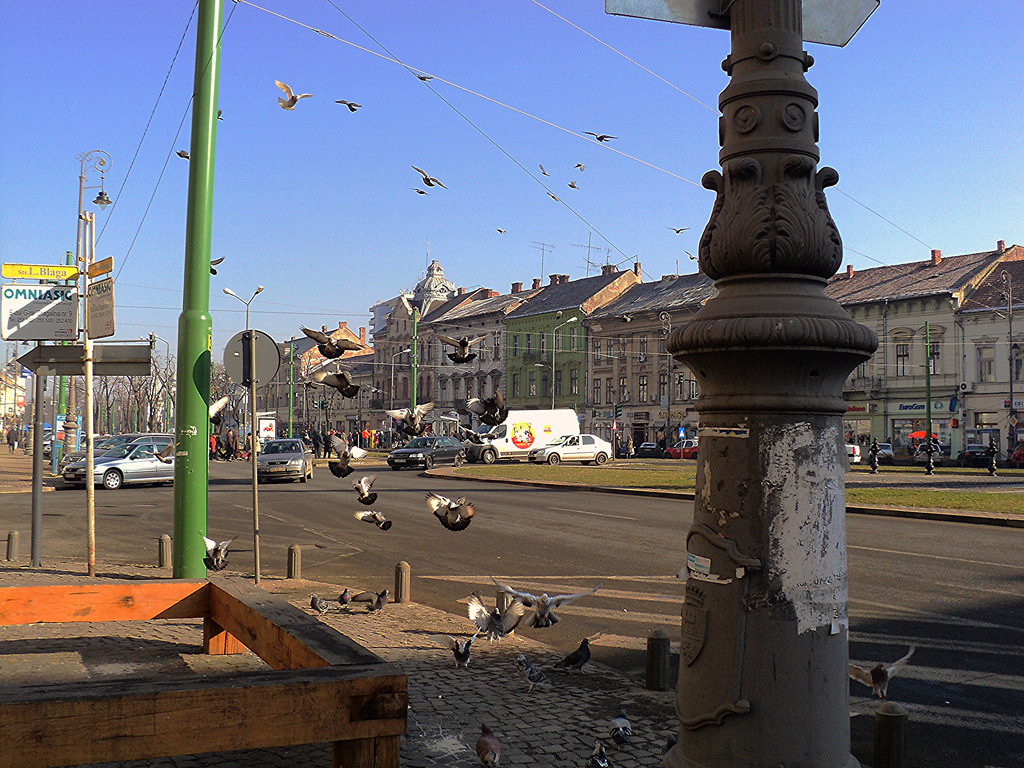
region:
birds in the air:
[277, 39, 619, 230]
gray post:
[705, 56, 882, 690]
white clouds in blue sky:
[881, 90, 938, 160]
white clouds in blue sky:
[909, 37, 985, 94]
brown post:
[712, 29, 864, 750]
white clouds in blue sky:
[265, 203, 322, 252]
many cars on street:
[217, 361, 620, 526]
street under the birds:
[473, 461, 636, 579]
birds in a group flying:
[336, 473, 485, 546]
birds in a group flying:
[337, 459, 492, 555]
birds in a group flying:
[334, 464, 506, 563]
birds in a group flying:
[339, 476, 479, 544]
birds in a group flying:
[337, 462, 480, 545]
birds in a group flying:
[333, 459, 485, 545]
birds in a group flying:
[317, 458, 488, 550]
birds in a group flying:
[320, 456, 483, 548]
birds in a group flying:
[329, 459, 495, 546]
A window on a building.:
[929, 336, 946, 371]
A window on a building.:
[638, 370, 649, 402]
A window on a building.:
[619, 373, 632, 403]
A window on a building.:
[606, 374, 616, 398]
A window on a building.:
[590, 378, 600, 404]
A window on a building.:
[569, 368, 582, 388]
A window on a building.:
[552, 329, 566, 353]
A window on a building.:
[541, 333, 546, 356]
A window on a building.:
[522, 336, 533, 356]